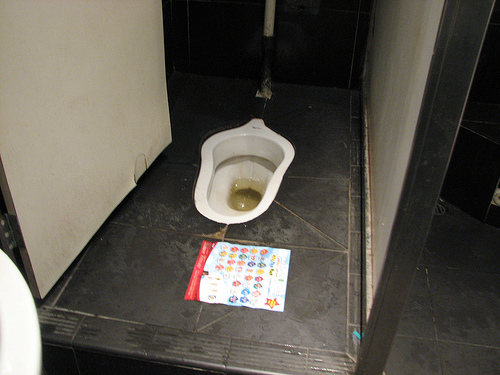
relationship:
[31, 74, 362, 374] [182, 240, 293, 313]
floor has paper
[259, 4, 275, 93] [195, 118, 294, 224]
tube over toilet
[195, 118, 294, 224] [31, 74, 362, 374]
toilet on floor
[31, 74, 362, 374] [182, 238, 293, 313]
floor has a paper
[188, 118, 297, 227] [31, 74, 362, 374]
toilet on floor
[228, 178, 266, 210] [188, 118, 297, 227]
water in toilet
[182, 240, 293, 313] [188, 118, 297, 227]
paper next to toilet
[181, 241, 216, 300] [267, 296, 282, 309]
page has a star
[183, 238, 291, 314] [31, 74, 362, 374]
sticker on floor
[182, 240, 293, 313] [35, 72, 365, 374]
paper on ground